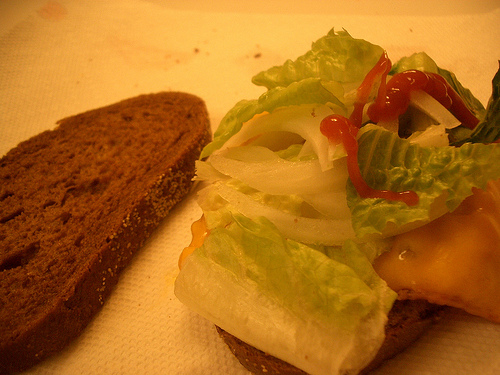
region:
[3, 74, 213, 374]
Brown bread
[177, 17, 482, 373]
Lettuce over brown bread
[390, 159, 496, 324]
Slice of cheese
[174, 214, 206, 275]
Piece of slice of cheese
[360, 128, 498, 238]
Green leaves of lettuce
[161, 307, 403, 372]
Stem of lettuce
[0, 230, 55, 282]
Hole in bread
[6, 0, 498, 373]
Sandwich is on a white cloth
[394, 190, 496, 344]
Cheese stick out of bread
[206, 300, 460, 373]
Slice of bread under letucce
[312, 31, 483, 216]
ketchup squiggles on top of lettuce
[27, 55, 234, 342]
dark bread next to lettuce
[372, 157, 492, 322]
bubbles on melting cheese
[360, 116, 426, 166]
white ribs on green lettuce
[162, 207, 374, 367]
white lettuce stem connected to pale green leaves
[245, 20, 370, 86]
jagged edge of lettuce leaf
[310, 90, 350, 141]
red dot of ketchup on top of sandwich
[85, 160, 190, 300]
tiny seeds on bottom of bread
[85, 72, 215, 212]
curved end of a slice of bread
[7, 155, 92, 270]
holes on surface of bread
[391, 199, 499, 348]
Piece of cheese over bread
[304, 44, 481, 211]
Ketchup over the lettuce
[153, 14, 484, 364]
Lettuce on a bread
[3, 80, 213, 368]
Slice of brown bread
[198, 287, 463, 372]
Slice of bread below lettuce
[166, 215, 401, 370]
Piece of lettuce on side of bread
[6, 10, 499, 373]
Sandwich is on a white napkin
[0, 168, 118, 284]
Bread has small wholes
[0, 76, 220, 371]
Bread to put on top of lettuce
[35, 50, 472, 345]
An open sandwich on a white towel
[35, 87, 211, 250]
Brown bread on a white towel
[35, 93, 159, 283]
A slice of bread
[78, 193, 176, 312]
The edge of a slice of brown bread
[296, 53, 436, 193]
Ketchup on green lettuce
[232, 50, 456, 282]
Ketchup and lettuce on cheese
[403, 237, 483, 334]
Yellow cheese on a sandwich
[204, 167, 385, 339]
A pile of lettuce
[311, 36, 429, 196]
Red ketchup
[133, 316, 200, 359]
A white towel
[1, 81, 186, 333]
this is a slice of bread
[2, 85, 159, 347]
the slice of bread is brown in color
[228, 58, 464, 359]
this is vegetable is beside the slice of bread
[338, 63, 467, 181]
tomato is on the vegetable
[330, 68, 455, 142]
the tomato is red in color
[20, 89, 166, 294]
the bread is dry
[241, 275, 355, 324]
the vegetables are fresh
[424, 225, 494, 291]
the cream is between the vegetables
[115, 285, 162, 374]
the saviet is white in color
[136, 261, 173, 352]
the food is on a saviet